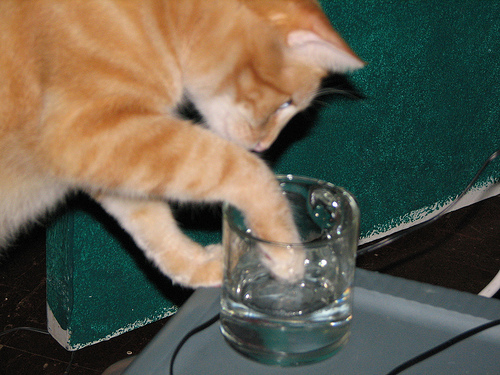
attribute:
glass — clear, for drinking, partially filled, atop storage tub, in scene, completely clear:
[221, 174, 356, 364]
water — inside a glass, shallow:
[231, 271, 348, 344]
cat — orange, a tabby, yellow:
[3, 2, 361, 289]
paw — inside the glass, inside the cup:
[260, 239, 310, 286]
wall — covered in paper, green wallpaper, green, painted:
[355, 16, 499, 234]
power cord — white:
[472, 269, 500, 297]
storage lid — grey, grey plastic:
[119, 251, 497, 371]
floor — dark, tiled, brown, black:
[363, 188, 499, 304]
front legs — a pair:
[84, 118, 308, 286]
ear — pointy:
[289, 30, 364, 75]